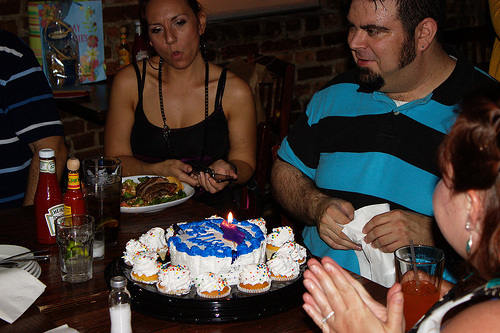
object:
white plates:
[0, 245, 46, 284]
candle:
[220, 210, 243, 242]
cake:
[167, 215, 269, 274]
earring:
[461, 223, 479, 256]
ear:
[461, 191, 485, 230]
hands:
[317, 187, 452, 257]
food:
[120, 173, 189, 209]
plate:
[117, 164, 197, 214]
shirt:
[276, 55, 499, 297]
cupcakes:
[120, 210, 317, 298]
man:
[269, 3, 499, 287]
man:
[0, 29, 67, 206]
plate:
[117, 170, 197, 215]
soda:
[400, 278, 438, 331]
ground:
[0, 1, 499, 154]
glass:
[83, 157, 125, 245]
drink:
[90, 182, 123, 278]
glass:
[391, 243, 447, 331]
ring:
[320, 310, 334, 325]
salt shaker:
[108, 276, 133, 331]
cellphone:
[192, 163, 234, 183]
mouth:
[168, 50, 184, 58]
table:
[53, 286, 95, 313]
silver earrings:
[463, 221, 475, 258]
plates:
[1, 241, 44, 285]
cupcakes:
[124, 207, 318, 302]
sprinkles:
[159, 264, 191, 297]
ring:
[320, 306, 335, 323]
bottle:
[31, 147, 66, 247]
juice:
[56, 212, 95, 286]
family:
[2, 2, 496, 333]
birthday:
[122, 209, 306, 300]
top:
[119, 59, 242, 154]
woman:
[295, 90, 500, 333]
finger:
[299, 262, 357, 333]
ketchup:
[39, 162, 67, 244]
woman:
[100, 23, 266, 194]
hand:
[196, 157, 238, 194]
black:
[300, 88, 493, 200]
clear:
[107, 275, 136, 333]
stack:
[17, 236, 54, 274]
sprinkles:
[121, 211, 290, 313]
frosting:
[180, 254, 262, 333]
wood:
[174, 323, 271, 333]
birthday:
[173, 206, 263, 271]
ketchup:
[38, 162, 71, 243]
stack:
[3, 243, 46, 332]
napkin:
[0, 265, 44, 333]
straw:
[403, 235, 421, 275]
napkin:
[339, 202, 415, 289]